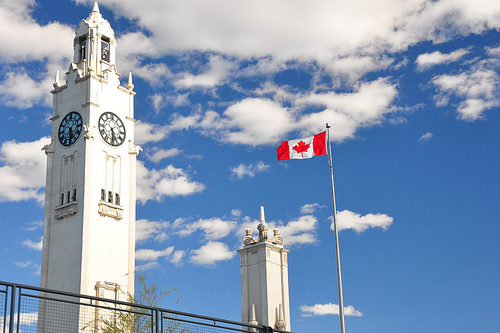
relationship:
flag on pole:
[275, 128, 329, 161] [325, 122, 353, 332]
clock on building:
[97, 111, 132, 149] [39, 3, 142, 332]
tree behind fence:
[82, 273, 188, 332] [1, 276, 299, 332]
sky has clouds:
[0, 0, 499, 332] [170, 78, 400, 151]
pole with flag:
[325, 122, 353, 332] [275, 128, 329, 161]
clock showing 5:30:
[97, 111, 132, 149] [108, 125, 122, 143]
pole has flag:
[325, 122, 353, 332] [275, 128, 329, 161]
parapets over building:
[51, 59, 134, 92] [39, 3, 142, 332]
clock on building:
[58, 111, 84, 146] [39, 3, 142, 332]